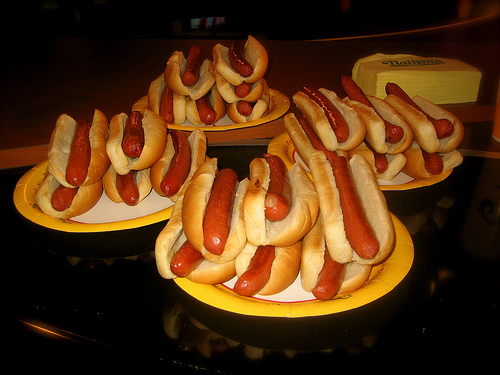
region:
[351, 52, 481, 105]
stack of white napkins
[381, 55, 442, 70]
logo on top of napkin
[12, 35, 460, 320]
four plates of hot dogs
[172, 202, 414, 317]
yellow and white paper plate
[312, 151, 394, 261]
cooked hot dog in bun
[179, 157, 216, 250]
top of brown bun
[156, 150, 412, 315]
six hot dogs on plate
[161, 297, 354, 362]
reflection on black surface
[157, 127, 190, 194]
curved hot dog in bun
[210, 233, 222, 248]
light reflection on skin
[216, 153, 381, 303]
This is a plate of hot dogs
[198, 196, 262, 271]
This is a lot of food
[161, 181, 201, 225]
This is a bun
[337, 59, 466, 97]
This is a stack of napkins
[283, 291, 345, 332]
This is a large plate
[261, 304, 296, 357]
The plate is paper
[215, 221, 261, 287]
The hot dogs are red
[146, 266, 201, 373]
This is a table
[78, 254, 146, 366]
The table is black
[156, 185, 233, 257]
The hot dogs are plain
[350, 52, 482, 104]
a stack of yellow napkins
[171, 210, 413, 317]
a paper plate full of hot dogs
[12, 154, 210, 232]
a paper plate full of hot dogs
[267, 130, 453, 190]
a paper plate full of hot dogs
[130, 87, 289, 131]
a paper plate full of hot dogs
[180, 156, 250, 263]
a hot dog in a bun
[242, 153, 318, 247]
a hot dog in a bun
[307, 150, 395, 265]
a hot dog in a bun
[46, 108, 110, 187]
a hot dog in a bun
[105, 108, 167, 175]
a hot dog in a bun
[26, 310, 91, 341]
light reflecting on black surface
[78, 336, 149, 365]
black edge of surface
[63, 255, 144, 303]
black surface on table top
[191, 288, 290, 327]
edge of yellow plate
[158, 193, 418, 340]
large round yellow plate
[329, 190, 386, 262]
brown long hot dog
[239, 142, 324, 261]
hot dog on plate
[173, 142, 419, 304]
plate filled with hot dogs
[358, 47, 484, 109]
pad of yellow butter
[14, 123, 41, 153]
edge of brown wood surface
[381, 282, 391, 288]
part of a plate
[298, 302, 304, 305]
edge of a plate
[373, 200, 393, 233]
part of a bread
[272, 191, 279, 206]
part of a sausage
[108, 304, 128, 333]
part of a table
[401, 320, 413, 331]
edge of a table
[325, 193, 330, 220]
part of a bread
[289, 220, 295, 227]
edge of a bread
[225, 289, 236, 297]
edge of a plate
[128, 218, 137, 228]
side of a plate